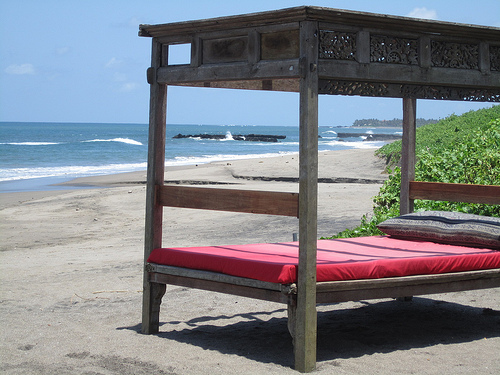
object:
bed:
[138, 4, 498, 373]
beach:
[0, 147, 497, 374]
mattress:
[146, 234, 499, 282]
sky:
[0, 0, 497, 127]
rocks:
[170, 133, 287, 142]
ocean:
[0, 121, 427, 186]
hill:
[321, 104, 498, 238]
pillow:
[375, 208, 499, 249]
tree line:
[352, 118, 445, 127]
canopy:
[134, 5, 499, 102]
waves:
[224, 130, 234, 140]